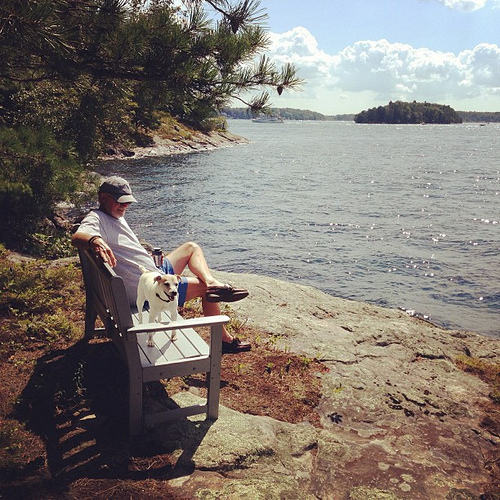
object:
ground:
[0, 260, 499, 499]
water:
[201, 122, 499, 231]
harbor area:
[62, 148, 227, 270]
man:
[70, 175, 251, 355]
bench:
[75, 239, 229, 436]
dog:
[135, 266, 182, 347]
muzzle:
[165, 286, 177, 301]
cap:
[100, 176, 139, 204]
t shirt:
[76, 209, 150, 307]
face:
[112, 201, 128, 219]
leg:
[168, 241, 249, 304]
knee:
[198, 279, 211, 297]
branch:
[1, 23, 295, 92]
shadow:
[12, 339, 205, 483]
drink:
[152, 248, 162, 268]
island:
[354, 99, 463, 124]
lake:
[68, 117, 500, 341]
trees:
[378, 105, 384, 120]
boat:
[251, 112, 285, 124]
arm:
[70, 213, 118, 262]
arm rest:
[125, 313, 232, 331]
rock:
[148, 390, 318, 470]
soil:
[220, 349, 325, 420]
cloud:
[331, 40, 499, 101]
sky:
[291, 1, 499, 84]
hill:
[221, 107, 354, 121]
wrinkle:
[122, 245, 146, 252]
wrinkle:
[113, 221, 135, 239]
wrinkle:
[120, 255, 140, 266]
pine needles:
[249, 14, 268, 23]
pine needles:
[258, 92, 266, 100]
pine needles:
[286, 67, 294, 78]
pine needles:
[202, 18, 213, 27]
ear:
[153, 275, 162, 283]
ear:
[176, 274, 182, 282]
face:
[154, 274, 182, 301]